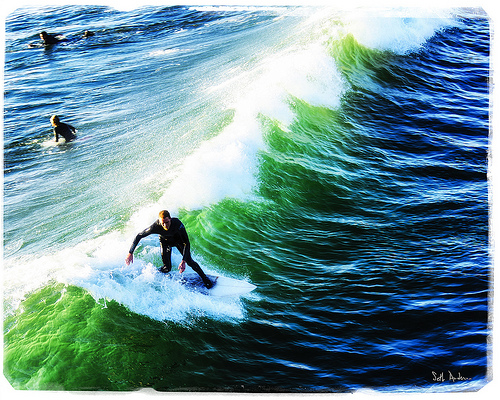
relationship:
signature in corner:
[430, 369, 474, 383] [408, 341, 497, 399]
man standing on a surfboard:
[130, 207, 210, 289] [168, 269, 257, 298]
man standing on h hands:
[130, 207, 210, 289] [124, 252, 187, 274]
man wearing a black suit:
[130, 207, 210, 289] [160, 231, 185, 250]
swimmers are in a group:
[30, 26, 126, 51] [32, 25, 115, 60]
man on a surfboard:
[125, 210, 214, 290] [168, 269, 257, 298]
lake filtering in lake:
[0, 0, 490, 392] [0, 0, 490, 392]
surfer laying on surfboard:
[29, 29, 69, 55] [53, 35, 71, 41]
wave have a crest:
[299, 99, 484, 353] [256, 47, 375, 88]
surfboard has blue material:
[168, 269, 257, 298] [180, 269, 210, 293]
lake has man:
[0, 0, 490, 392] [125, 210, 214, 290]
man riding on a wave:
[125, 210, 214, 290] [106, 257, 247, 332]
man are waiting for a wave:
[125, 210, 214, 290] [214, 61, 346, 218]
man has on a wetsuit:
[125, 210, 214, 290] [160, 231, 185, 250]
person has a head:
[130, 207, 210, 289] [157, 205, 172, 226]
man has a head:
[28, 31, 66, 50] [40, 29, 49, 43]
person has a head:
[51, 112, 80, 147] [50, 112, 59, 129]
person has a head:
[78, 29, 112, 40] [82, 29, 95, 38]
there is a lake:
[286, 79, 436, 268] [282, 79, 470, 343]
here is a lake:
[136, 23, 377, 132] [282, 79, 470, 343]